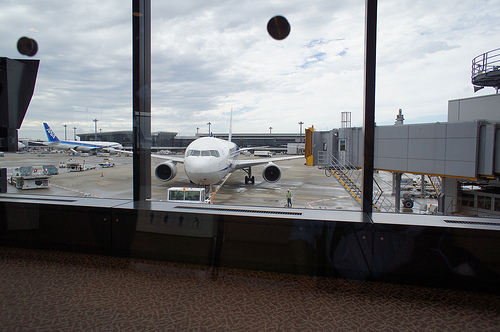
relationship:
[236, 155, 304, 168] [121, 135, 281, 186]
left wing on an airplane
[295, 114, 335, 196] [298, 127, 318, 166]
door on belt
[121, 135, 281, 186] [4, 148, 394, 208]
an airplane on tarmac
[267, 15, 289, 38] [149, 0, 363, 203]
circle on glass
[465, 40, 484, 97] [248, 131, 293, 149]
balcony over building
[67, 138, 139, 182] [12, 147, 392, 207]
truck on tarmac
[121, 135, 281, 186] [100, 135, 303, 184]
an airplane at airport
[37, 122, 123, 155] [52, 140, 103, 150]
plane with stripe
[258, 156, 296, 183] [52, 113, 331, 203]
engine on plane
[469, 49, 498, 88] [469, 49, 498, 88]
balcony on balcony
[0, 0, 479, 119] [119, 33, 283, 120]
air has clouds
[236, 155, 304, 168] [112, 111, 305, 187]
left wing of plane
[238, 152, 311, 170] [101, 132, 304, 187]
left wing of plane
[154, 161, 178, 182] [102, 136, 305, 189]
engine of plane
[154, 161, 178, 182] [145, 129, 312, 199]
engine of plane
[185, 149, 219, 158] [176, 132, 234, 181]
windows of cockpit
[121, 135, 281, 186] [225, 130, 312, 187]
an airplane to runway